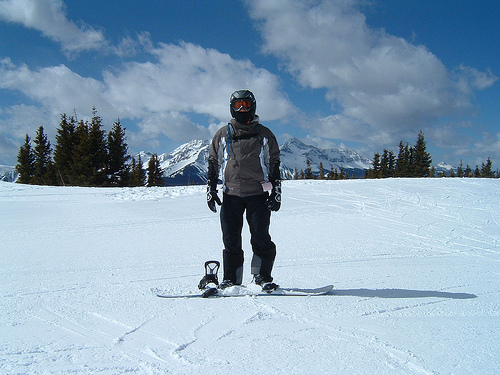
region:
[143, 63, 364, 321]
a snowboarder looking at the camera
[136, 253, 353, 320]
a snowboard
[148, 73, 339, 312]
a young man with a snowboard on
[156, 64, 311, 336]
a man standing in the snow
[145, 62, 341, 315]
a young person wearing a dark ski outfit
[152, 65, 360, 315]
a young person ready to go snowboarding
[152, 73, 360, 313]
a young person wearing a ski outfit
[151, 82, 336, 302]
The person is on a snowboard.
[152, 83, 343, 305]
The snowboarder is wearing a helmet.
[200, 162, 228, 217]
The snowboarder is wearing gloves.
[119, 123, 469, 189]
The mountains are covered in snow.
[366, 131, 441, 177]
Trees are in the background.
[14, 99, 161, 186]
Trees are in front of the mountains.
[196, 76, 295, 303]
The snowboarder is in black and grey.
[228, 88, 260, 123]
The helmet is black with goggles.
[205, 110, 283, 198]
The jacket is grey and white.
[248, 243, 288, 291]
The snowboots are black and grey.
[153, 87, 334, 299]
man standing on a snowboard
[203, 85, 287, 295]
man wearing a gray coat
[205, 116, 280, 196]
coat with white side stripes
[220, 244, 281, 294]
black and gray snow boots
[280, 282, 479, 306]
shadow of a man on the snow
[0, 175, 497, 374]
ground covered in snow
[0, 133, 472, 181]
mountain range covered in snow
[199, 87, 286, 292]
man wearing black pants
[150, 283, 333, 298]
snowboard covered with snow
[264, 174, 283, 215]
black glove with white design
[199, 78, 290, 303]
a man in a mask stands in the snow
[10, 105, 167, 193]
a collection of trees in the winter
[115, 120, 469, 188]
a mountain scape covered in snow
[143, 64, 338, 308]
a man on a snowboard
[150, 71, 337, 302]
a snowboarder poses on his board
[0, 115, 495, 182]
a mountainous forest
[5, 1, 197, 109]
clouds flying over a blue sky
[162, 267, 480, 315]
the shadow of a man on a snowboard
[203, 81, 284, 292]
a man dressed to go snowboarding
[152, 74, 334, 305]
a man steps into place on his snowboard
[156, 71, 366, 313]
a snowboarder having his picture taken